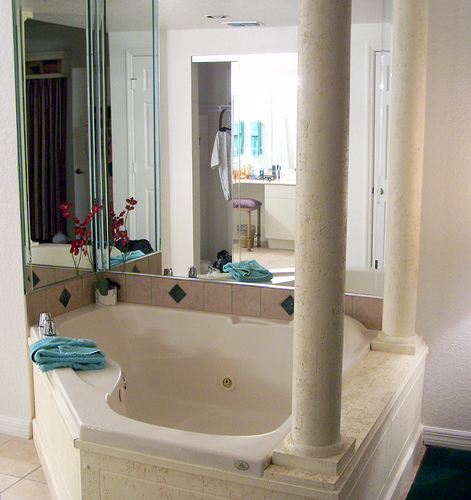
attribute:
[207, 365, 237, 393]
drain — water 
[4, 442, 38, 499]
tile — light brown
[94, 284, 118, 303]
cup — corner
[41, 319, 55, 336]
knob — silver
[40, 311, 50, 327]
knob — silver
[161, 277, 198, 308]
triangle — shape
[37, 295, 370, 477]
whirlpool tub — large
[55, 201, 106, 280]
plant — pink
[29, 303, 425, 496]
tub — bath 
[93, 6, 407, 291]
mirror — huge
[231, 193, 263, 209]
cushion — purple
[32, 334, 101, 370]
towel — blue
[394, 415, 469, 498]
rug — black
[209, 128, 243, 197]
shirt — white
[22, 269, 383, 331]
tiling — decorative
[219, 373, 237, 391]
spout — jet 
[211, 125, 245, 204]
shirt — white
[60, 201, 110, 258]
flowers — red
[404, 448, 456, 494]
tile — green , triangle